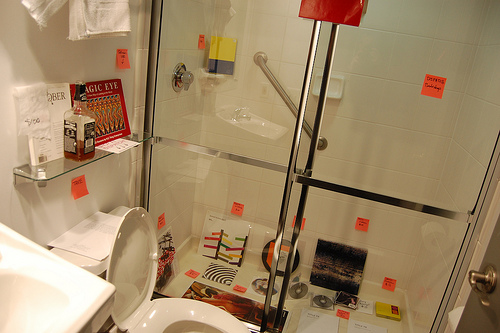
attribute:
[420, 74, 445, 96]
post-it — neon, red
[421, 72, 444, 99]
red post-it — neon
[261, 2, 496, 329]
shower door — glass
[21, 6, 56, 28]
hand towel — white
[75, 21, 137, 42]
hand towel — white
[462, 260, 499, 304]
knob — nickel plated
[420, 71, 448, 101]
post-it note — orange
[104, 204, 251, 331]
toilet seat — open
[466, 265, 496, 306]
handle — silver, door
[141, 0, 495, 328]
shower — stand up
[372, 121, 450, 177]
shower tiles — white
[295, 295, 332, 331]
paper — white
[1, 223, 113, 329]
sink — white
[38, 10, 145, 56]
towel — white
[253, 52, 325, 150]
handle — silver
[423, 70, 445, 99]
post-it — orange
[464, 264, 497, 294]
handle — metallic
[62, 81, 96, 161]
bottle — half filled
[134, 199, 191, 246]
post-it — orange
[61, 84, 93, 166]
glass — half filled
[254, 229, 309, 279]
cover — clear